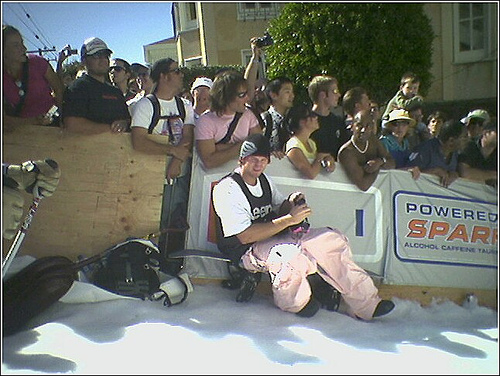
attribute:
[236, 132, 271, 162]
hat — black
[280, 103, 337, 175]
woman — wearing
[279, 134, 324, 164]
shirt — yellow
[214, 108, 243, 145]
strap — black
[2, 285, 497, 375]
snow — white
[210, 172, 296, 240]
shirt — white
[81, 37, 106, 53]
hat — white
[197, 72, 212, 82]
hat — white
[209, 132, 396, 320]
man — wearing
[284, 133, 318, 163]
shirt — yellow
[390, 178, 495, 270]
sign — white, orange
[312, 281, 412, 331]
shoes — black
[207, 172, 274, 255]
vest — black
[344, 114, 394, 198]
man — wearing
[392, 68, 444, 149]
boy — small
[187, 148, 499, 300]
sign — long, white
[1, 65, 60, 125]
woman shirt — pink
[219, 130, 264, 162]
cap — black, gray, knit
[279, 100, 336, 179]
person — standing, behind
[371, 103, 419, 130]
hat — brown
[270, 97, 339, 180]
woman — wearing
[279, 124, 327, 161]
shirt — yellow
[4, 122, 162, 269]
board — brown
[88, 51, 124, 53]
brim — medium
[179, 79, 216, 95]
brim — medium